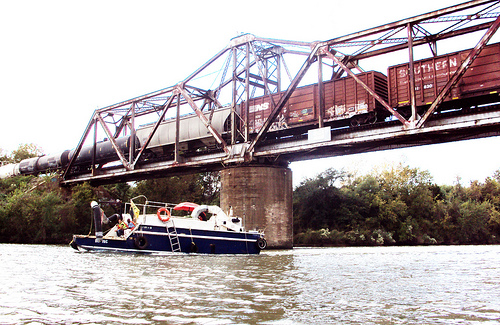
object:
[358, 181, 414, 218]
leaves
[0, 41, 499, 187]
train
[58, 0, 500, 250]
bridge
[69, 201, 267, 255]
boat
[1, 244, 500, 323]
water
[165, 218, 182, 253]
ladder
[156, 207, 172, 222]
life preserver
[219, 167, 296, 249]
pillar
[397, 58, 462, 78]
writing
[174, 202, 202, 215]
umbrella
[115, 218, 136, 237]
people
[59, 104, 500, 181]
tracks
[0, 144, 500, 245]
trees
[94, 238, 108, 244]
writing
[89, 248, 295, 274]
shadows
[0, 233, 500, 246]
rocks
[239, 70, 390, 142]
box car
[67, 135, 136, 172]
tanker